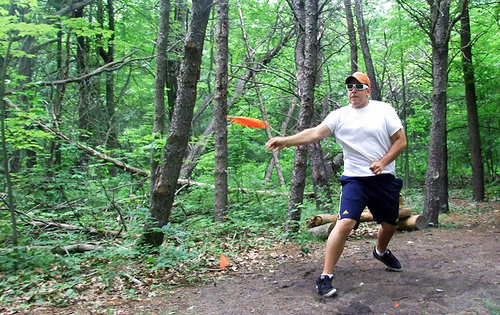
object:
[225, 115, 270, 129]
frisbee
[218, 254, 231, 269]
flag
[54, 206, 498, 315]
ground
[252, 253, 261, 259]
leaves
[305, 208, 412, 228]
logs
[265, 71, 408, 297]
man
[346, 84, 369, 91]
sunglasses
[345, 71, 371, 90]
hat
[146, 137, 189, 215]
trunk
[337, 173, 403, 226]
shorts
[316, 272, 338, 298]
sneakers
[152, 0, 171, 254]
tree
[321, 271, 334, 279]
sock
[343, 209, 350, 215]
logo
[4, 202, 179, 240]
shrubs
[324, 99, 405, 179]
shirt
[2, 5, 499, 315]
forest